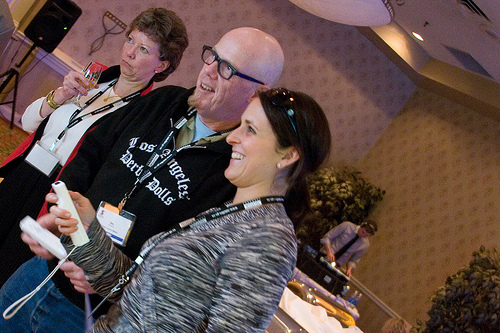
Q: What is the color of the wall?
A: Brown.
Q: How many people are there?
A: 4.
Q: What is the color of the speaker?
A: Black.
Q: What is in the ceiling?
A: Lights.